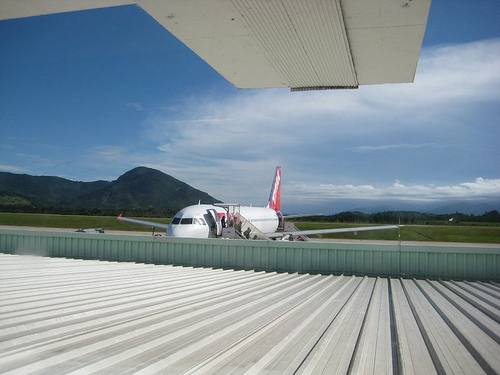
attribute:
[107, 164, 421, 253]
tail fin — red